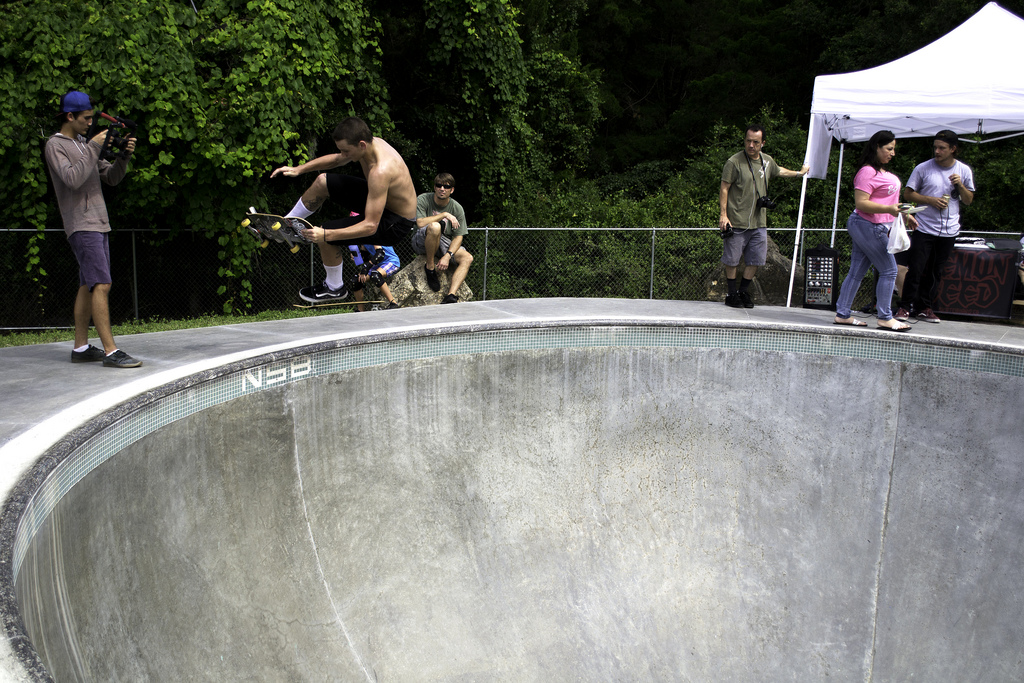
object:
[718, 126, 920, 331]
up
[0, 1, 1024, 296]
woods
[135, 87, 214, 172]
leaves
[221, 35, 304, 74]
leaves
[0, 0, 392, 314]
tree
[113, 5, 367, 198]
tree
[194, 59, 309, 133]
leaves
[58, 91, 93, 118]
cap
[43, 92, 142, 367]
man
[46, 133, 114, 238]
shirt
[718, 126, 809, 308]
person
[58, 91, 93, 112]
hat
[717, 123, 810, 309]
man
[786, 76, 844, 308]
pole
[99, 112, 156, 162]
camera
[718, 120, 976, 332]
tent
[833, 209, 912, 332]
underneath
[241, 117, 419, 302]
man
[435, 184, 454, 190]
sunglasses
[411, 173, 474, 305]
man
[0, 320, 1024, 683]
pit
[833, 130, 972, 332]
talking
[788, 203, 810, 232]
tent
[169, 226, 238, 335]
fence